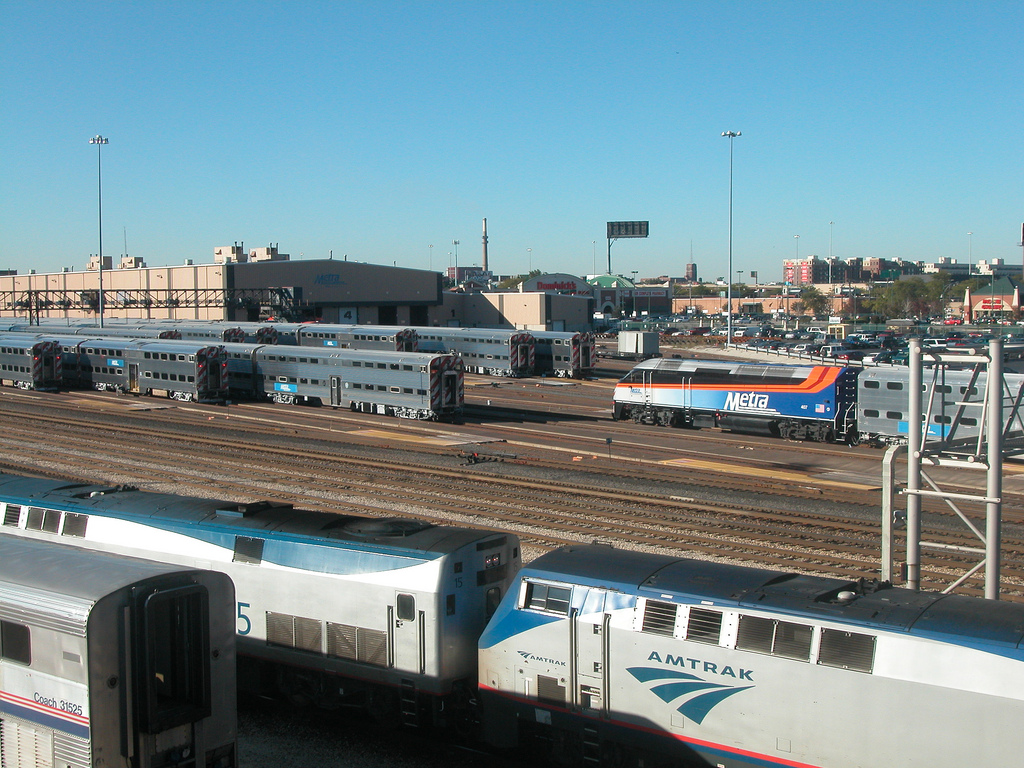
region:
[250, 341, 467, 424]
double decker passenger train car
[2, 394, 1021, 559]
empty line of railroad tracks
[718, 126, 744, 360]
tall gray street lights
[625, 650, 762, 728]
Amtrak logo on the side of the train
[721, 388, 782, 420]
Metra logo on the side of train engine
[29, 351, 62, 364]
red lights on back of train car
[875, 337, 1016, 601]
metal pole standing up in between train tracks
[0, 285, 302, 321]
black metal bridge over tracks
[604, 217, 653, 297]
black metal sign is tall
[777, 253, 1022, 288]
group of buildings in the background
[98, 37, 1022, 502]
Blue sky in the background.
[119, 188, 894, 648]
Buildings by the tracks.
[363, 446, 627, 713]
Train on the tracks.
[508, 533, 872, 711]
Windows on the train.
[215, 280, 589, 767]
Tracks with trains on it.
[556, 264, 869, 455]
Blue and orange train.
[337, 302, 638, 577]
Gravel on the tracks.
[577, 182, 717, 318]
Sign over the building.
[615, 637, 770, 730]
logo is blue in color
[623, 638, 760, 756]
logo on side of the train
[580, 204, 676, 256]
sign on a pole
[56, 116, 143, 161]
lights on a pole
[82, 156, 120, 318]
pole with lights on it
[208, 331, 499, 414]
train is grey in color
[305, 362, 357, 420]
door on side of train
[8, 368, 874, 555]
train tracks are brown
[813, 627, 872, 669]
glass window on the train engine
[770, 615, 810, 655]
glass window on the train engine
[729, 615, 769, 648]
glass window on the train engine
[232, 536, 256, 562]
glass window on the train engine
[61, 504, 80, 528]
glass window on the train engine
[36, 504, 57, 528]
glass window on the train engine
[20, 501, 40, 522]
glass window on the train engine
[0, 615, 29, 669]
glass window on the train engine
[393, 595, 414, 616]
glass window on the train engine